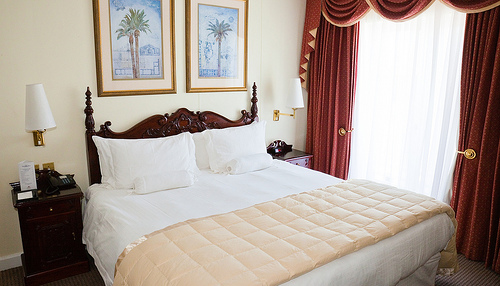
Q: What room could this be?
A: It is a bedroom.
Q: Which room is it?
A: It is a bedroom.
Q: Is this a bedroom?
A: Yes, it is a bedroom.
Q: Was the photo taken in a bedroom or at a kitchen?
A: It was taken at a bedroom.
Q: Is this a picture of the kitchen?
A: No, the picture is showing the bedroom.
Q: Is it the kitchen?
A: No, it is the bedroom.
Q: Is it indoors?
A: Yes, it is indoors.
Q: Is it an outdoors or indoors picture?
A: It is indoors.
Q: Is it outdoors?
A: No, it is indoors.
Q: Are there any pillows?
A: Yes, there is a pillow.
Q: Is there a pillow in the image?
A: Yes, there is a pillow.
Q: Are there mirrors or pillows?
A: Yes, there is a pillow.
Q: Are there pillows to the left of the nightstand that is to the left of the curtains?
A: Yes, there is a pillow to the left of the nightstand.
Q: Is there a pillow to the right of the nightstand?
A: No, the pillow is to the left of the nightstand.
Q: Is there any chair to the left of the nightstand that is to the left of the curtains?
A: No, there is a pillow to the left of the nightstand.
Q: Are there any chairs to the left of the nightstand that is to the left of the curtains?
A: No, there is a pillow to the left of the nightstand.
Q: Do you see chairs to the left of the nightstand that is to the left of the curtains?
A: No, there is a pillow to the left of the nightstand.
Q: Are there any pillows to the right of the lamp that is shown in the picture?
A: Yes, there is a pillow to the right of the lamp.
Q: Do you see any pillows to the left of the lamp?
A: No, the pillow is to the right of the lamp.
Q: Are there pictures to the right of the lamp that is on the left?
A: No, there is a pillow to the right of the lamp.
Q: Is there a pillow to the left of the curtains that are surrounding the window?
A: Yes, there is a pillow to the left of the curtains.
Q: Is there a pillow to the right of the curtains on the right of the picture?
A: No, the pillow is to the left of the curtains.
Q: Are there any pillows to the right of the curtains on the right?
A: No, the pillow is to the left of the curtains.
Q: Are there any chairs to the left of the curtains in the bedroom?
A: No, there is a pillow to the left of the curtains.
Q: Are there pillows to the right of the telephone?
A: Yes, there is a pillow to the right of the telephone.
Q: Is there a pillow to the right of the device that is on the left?
A: Yes, there is a pillow to the right of the telephone.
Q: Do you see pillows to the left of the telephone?
A: No, the pillow is to the right of the telephone.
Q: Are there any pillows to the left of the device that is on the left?
A: No, the pillow is to the right of the telephone.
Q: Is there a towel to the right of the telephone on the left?
A: No, there is a pillow to the right of the telephone.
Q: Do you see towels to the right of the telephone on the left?
A: No, there is a pillow to the right of the telephone.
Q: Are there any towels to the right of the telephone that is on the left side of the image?
A: No, there is a pillow to the right of the telephone.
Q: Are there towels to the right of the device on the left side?
A: No, there is a pillow to the right of the telephone.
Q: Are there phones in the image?
A: Yes, there is a phone.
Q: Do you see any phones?
A: Yes, there is a phone.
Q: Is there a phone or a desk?
A: Yes, there is a phone.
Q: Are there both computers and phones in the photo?
A: No, there is a phone but no computers.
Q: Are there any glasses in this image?
A: No, there are no glasses.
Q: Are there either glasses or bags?
A: No, there are no glasses or bags.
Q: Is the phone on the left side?
A: Yes, the phone is on the left of the image.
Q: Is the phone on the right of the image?
A: No, the phone is on the left of the image.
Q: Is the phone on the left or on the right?
A: The phone is on the left of the image.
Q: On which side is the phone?
A: The phone is on the left of the image.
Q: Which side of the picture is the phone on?
A: The phone is on the left of the image.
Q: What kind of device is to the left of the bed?
A: The device is a phone.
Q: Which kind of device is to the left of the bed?
A: The device is a phone.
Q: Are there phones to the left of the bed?
A: Yes, there is a phone to the left of the bed.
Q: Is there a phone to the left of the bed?
A: Yes, there is a phone to the left of the bed.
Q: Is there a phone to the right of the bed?
A: No, the phone is to the left of the bed.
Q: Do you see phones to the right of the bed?
A: No, the phone is to the left of the bed.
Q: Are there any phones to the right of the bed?
A: No, the phone is to the left of the bed.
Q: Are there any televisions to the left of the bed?
A: No, there is a phone to the left of the bed.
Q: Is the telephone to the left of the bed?
A: Yes, the telephone is to the left of the bed.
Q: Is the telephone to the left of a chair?
A: No, the telephone is to the left of the bed.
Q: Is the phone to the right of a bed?
A: No, the phone is to the left of a bed.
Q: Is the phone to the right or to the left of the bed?
A: The phone is to the left of the bed.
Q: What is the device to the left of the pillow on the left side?
A: The device is a phone.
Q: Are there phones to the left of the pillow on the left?
A: Yes, there is a phone to the left of the pillow.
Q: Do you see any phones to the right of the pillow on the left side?
A: No, the phone is to the left of the pillow.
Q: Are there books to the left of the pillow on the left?
A: No, there is a phone to the left of the pillow.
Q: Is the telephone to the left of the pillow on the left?
A: Yes, the telephone is to the left of the pillow.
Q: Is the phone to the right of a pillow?
A: No, the phone is to the left of a pillow.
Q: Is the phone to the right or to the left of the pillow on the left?
A: The phone is to the left of the pillow.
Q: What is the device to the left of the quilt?
A: The device is a phone.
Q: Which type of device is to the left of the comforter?
A: The device is a phone.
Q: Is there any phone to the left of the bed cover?
A: Yes, there is a phone to the left of the bed cover.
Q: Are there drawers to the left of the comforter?
A: No, there is a phone to the left of the comforter.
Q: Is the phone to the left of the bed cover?
A: Yes, the phone is to the left of the bed cover.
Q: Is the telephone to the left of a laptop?
A: No, the telephone is to the left of the bed cover.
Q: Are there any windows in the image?
A: Yes, there is a window.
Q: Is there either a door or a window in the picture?
A: Yes, there is a window.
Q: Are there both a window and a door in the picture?
A: No, there is a window but no doors.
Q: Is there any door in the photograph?
A: No, there are no doors.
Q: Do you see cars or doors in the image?
A: No, there are no doors or cars.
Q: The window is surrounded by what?
A: The window is surrounded by the curtains.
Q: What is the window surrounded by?
A: The window is surrounded by the curtains.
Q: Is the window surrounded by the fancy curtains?
A: Yes, the window is surrounded by the curtains.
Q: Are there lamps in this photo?
A: Yes, there is a lamp.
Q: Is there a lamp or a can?
A: Yes, there is a lamp.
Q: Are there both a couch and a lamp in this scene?
A: No, there is a lamp but no couches.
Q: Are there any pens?
A: No, there are no pens.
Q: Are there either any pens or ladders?
A: No, there are no pens or ladders.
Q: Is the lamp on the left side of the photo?
A: Yes, the lamp is on the left of the image.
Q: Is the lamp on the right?
A: No, the lamp is on the left of the image.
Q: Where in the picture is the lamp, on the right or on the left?
A: The lamp is on the left of the image.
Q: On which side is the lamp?
A: The lamp is on the left of the image.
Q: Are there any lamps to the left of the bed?
A: Yes, there is a lamp to the left of the bed.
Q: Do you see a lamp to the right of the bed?
A: No, the lamp is to the left of the bed.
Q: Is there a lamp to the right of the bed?
A: No, the lamp is to the left of the bed.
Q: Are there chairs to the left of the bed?
A: No, there is a lamp to the left of the bed.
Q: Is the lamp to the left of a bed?
A: Yes, the lamp is to the left of a bed.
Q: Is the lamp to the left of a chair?
A: No, the lamp is to the left of a bed.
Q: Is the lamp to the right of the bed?
A: No, the lamp is to the left of the bed.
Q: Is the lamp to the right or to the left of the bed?
A: The lamp is to the left of the bed.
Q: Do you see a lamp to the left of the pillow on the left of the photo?
A: Yes, there is a lamp to the left of the pillow.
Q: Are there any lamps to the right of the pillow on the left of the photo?
A: No, the lamp is to the left of the pillow.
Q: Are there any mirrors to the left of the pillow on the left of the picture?
A: No, there is a lamp to the left of the pillow.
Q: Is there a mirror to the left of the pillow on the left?
A: No, there is a lamp to the left of the pillow.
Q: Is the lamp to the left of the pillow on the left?
A: Yes, the lamp is to the left of the pillow.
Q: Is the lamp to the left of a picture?
A: No, the lamp is to the left of the pillow.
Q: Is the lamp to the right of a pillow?
A: No, the lamp is to the left of a pillow.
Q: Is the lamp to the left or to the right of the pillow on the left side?
A: The lamp is to the left of the pillow.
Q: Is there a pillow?
A: Yes, there is a pillow.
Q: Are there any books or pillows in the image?
A: Yes, there is a pillow.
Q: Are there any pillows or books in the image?
A: Yes, there is a pillow.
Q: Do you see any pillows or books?
A: Yes, there is a pillow.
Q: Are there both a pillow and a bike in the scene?
A: No, there is a pillow but no bikes.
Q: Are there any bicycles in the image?
A: No, there are no bicycles.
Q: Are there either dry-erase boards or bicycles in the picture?
A: No, there are no bicycles or dry-erase boards.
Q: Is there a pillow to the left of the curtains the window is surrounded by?
A: Yes, there is a pillow to the left of the curtains.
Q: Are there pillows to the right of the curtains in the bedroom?
A: No, the pillow is to the left of the curtains.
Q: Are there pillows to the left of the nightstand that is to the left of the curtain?
A: Yes, there is a pillow to the left of the nightstand.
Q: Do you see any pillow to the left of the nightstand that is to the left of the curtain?
A: Yes, there is a pillow to the left of the nightstand.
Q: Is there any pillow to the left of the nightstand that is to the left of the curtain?
A: Yes, there is a pillow to the left of the nightstand.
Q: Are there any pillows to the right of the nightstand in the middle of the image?
A: No, the pillow is to the left of the nightstand.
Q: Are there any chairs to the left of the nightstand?
A: No, there is a pillow to the left of the nightstand.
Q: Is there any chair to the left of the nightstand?
A: No, there is a pillow to the left of the nightstand.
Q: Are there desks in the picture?
A: Yes, there is a desk.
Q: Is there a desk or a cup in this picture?
A: Yes, there is a desk.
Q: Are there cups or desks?
A: Yes, there is a desk.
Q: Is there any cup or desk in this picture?
A: Yes, there is a desk.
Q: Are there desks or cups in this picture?
A: Yes, there is a desk.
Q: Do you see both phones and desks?
A: Yes, there are both a desk and a phone.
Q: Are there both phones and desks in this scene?
A: Yes, there are both a desk and a phone.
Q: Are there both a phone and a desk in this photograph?
A: Yes, there are both a desk and a phone.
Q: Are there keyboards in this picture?
A: No, there are no keyboards.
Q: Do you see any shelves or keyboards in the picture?
A: No, there are no keyboards or shelves.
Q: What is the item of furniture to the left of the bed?
A: The piece of furniture is a desk.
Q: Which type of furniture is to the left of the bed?
A: The piece of furniture is a desk.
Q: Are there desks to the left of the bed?
A: Yes, there is a desk to the left of the bed.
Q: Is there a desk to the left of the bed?
A: Yes, there is a desk to the left of the bed.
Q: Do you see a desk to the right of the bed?
A: No, the desk is to the left of the bed.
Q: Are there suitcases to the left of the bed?
A: No, there is a desk to the left of the bed.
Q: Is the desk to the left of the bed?
A: Yes, the desk is to the left of the bed.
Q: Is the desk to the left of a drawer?
A: No, the desk is to the left of the bed.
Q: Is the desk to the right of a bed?
A: No, the desk is to the left of a bed.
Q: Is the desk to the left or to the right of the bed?
A: The desk is to the left of the bed.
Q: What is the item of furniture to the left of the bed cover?
A: The piece of furniture is a desk.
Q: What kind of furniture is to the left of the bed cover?
A: The piece of furniture is a desk.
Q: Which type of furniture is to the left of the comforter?
A: The piece of furniture is a desk.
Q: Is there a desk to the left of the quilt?
A: Yes, there is a desk to the left of the quilt.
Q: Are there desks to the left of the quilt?
A: Yes, there is a desk to the left of the quilt.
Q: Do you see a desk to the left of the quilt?
A: Yes, there is a desk to the left of the quilt.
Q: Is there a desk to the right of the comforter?
A: No, the desk is to the left of the comforter.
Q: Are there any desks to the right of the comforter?
A: No, the desk is to the left of the comforter.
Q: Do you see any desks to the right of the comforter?
A: No, the desk is to the left of the comforter.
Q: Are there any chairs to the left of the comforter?
A: No, there is a desk to the left of the comforter.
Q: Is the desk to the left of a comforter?
A: Yes, the desk is to the left of a comforter.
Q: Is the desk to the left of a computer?
A: No, the desk is to the left of a comforter.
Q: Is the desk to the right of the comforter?
A: No, the desk is to the left of the comforter.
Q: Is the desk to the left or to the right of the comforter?
A: The desk is to the left of the comforter.